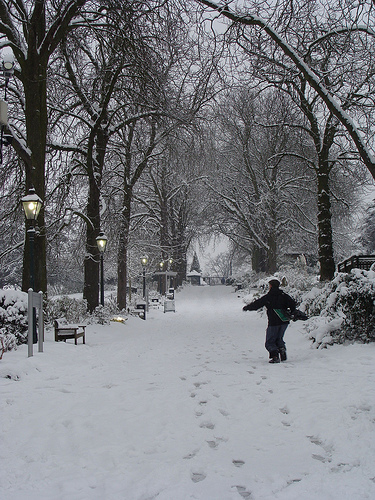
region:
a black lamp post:
[19, 186, 44, 343]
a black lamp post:
[94, 231, 109, 304]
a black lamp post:
[138, 251, 149, 294]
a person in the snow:
[243, 278, 307, 363]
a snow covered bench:
[54, 317, 87, 342]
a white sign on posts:
[27, 288, 46, 350]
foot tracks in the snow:
[180, 323, 365, 497]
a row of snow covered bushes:
[229, 248, 373, 349]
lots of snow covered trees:
[0, 0, 374, 310]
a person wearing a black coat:
[241, 276, 307, 364]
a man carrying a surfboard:
[240, 278, 307, 364]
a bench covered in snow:
[51, 316, 86, 345]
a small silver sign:
[25, 287, 44, 355]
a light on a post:
[20, 186, 40, 231]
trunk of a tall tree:
[84, 47, 107, 309]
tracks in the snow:
[180, 339, 338, 498]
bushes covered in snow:
[302, 270, 373, 343]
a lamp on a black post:
[93, 230, 107, 323]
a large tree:
[1, 0, 66, 311]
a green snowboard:
[273, 306, 307, 322]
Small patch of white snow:
[95, 395, 122, 428]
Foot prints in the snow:
[189, 368, 221, 446]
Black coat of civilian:
[268, 296, 284, 305]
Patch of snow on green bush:
[6, 303, 21, 324]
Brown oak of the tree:
[80, 276, 102, 301]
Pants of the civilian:
[266, 328, 288, 346]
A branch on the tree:
[151, 145, 168, 159]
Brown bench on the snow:
[53, 317, 87, 342]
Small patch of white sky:
[215, 23, 227, 32]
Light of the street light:
[20, 191, 41, 218]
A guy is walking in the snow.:
[240, 279, 306, 363]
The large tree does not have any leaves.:
[0, 0, 82, 296]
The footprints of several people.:
[178, 331, 306, 498]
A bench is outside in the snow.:
[53, 321, 87, 345]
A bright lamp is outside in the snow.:
[18, 187, 43, 226]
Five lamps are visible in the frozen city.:
[18, 186, 173, 268]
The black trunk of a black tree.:
[315, 148, 334, 281]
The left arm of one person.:
[240, 292, 266, 312]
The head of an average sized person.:
[266, 279, 280, 291]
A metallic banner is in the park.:
[26, 287, 43, 355]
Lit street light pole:
[20, 181, 46, 355]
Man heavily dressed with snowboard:
[242, 276, 313, 367]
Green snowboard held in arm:
[270, 305, 312, 322]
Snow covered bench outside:
[51, 315, 93, 346]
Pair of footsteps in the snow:
[178, 332, 245, 498]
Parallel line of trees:
[13, 139, 191, 317]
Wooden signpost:
[26, 287, 45, 355]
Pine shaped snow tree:
[190, 251, 203, 274]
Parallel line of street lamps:
[20, 183, 181, 343]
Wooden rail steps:
[336, 254, 373, 271]